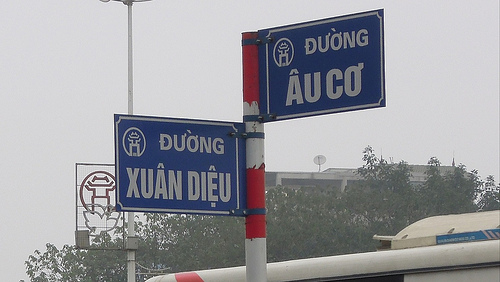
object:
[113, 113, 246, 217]
sign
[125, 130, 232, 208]
writing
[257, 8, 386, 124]
sign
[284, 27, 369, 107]
writing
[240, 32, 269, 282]
pole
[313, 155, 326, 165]
dish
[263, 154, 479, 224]
building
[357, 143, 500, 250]
tree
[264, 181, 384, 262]
tree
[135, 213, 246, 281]
tree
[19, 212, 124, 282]
tree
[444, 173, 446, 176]
foliage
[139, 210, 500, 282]
bus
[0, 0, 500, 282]
skies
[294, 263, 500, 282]
pipe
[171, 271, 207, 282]
mark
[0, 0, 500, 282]
view